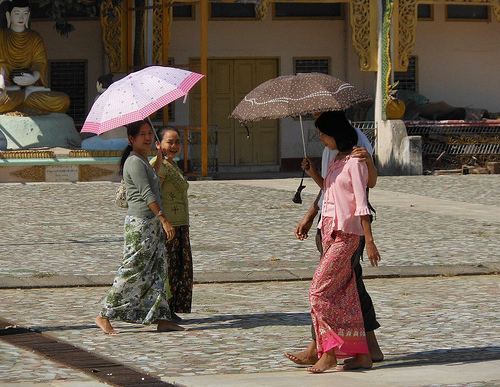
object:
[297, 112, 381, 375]
woman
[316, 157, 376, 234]
sweater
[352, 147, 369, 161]
hand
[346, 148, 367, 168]
shoulder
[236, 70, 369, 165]
umbrella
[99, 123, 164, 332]
woman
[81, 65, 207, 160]
umbrella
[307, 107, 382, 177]
man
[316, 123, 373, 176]
shirt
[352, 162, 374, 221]
sleeves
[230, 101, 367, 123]
ruffles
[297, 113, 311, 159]
handle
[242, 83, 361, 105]
design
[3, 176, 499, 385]
street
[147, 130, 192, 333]
woman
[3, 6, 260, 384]
left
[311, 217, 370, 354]
skirt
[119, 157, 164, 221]
jacket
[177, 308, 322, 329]
shadow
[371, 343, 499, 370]
shadow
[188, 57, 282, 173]
door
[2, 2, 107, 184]
statue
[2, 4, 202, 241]
corner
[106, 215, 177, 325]
skirt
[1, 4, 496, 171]
background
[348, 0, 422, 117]
decoration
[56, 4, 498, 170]
building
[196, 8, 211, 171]
pole